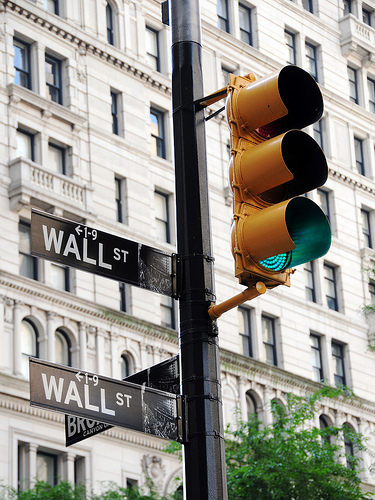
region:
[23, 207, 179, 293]
this is a sign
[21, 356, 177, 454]
this is a sign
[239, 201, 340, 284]
this is a traffic light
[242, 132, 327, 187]
this is a traffic light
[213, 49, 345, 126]
this is a traffic light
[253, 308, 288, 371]
this is a window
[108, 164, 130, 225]
this is a window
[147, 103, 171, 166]
this is a window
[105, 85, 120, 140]
this is a window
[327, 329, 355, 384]
this is a window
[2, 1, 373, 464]
the facade of a building on Wall Street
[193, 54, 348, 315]
a yellow traffic signal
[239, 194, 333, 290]
the green light on a traffic signal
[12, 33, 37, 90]
a window on a building on Wall Street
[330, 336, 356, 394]
a window on a building on Wall Street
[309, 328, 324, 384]
a window on a building on Wall Street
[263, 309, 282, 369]
a window on a building on Wall Street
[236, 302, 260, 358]
a window on a building on Wall Street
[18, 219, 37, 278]
a window on a building on Wall Street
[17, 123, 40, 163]
a window on a building on Wall Street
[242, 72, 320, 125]
this is a traffic light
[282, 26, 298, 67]
this is a window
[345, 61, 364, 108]
this is a window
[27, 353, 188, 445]
a metal sign saying Wall St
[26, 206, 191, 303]
a sign that says wall st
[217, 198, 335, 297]
a green stop light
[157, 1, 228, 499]
a metal pole holding a stop light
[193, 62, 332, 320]
a stop light on a pole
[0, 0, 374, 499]
a white building in the distance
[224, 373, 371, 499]
green shrubs in the distance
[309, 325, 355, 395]
a window on a white building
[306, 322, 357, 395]
a window on a building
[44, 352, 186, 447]
a sign with the word canyon on it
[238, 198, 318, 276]
The traffic light is green.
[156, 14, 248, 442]
The pole is black.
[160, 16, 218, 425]
The pole is metal.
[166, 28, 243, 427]
The pole is straight.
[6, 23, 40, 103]
The window is closed.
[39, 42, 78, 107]
The window is closed.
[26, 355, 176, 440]
The street sign is black.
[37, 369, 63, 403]
The letter is white.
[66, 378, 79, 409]
The letter is white.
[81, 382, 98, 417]
The letter is white.